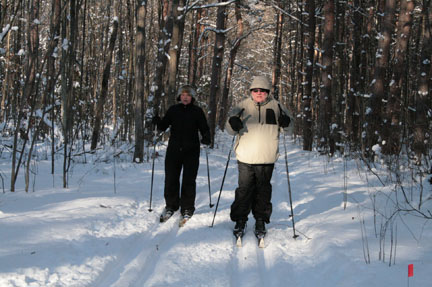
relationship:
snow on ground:
[2, 129, 431, 285] [61, 223, 251, 267]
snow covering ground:
[33, 201, 73, 224] [2, 129, 431, 285]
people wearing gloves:
[151, 70, 294, 238] [227, 111, 295, 133]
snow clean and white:
[2, 129, 431, 285] [1, 198, 143, 286]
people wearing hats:
[151, 70, 294, 238] [167, 70, 285, 108]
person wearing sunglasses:
[231, 70, 292, 238] [251, 87, 272, 98]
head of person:
[169, 78, 205, 107] [144, 73, 212, 224]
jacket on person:
[233, 72, 284, 165] [231, 70, 292, 238]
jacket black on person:
[151, 100, 210, 149] [144, 73, 212, 224]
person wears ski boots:
[231, 70, 292, 238] [234, 210, 272, 238]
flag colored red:
[395, 258, 425, 286] [406, 263, 417, 281]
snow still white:
[2, 129, 431, 285] [1, 198, 143, 286]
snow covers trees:
[2, 129, 431, 285] [1, 2, 432, 158]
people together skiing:
[151, 70, 294, 238] [145, 171, 313, 265]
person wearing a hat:
[231, 70, 292, 238] [251, 72, 277, 96]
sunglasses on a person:
[251, 87, 272, 98] [231, 70, 292, 238]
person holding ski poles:
[231, 70, 292, 238] [207, 133, 308, 242]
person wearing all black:
[144, 73, 212, 224] [172, 113, 199, 161]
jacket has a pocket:
[233, 72, 284, 165] [264, 106, 280, 129]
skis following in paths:
[219, 234, 272, 250] [92, 235, 306, 286]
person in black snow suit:
[144, 73, 212, 224] [156, 105, 216, 216]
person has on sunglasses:
[231, 70, 292, 238] [251, 87, 272, 98]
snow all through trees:
[2, 129, 431, 285] [1, 2, 432, 158]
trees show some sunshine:
[1, 2, 432, 158] [197, 9, 310, 69]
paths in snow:
[92, 235, 306, 286] [2, 129, 431, 285]